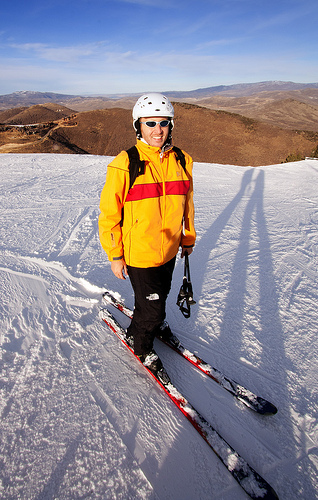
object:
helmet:
[130, 90, 176, 145]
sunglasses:
[146, 118, 171, 128]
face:
[139, 116, 170, 150]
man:
[98, 93, 196, 376]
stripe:
[127, 180, 191, 203]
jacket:
[98, 138, 196, 269]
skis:
[96, 292, 280, 500]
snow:
[0, 152, 316, 499]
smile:
[153, 135, 163, 140]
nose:
[156, 126, 163, 134]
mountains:
[0, 0, 317, 166]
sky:
[0, 0, 318, 102]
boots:
[131, 336, 162, 370]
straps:
[123, 145, 147, 191]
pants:
[127, 256, 175, 354]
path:
[0, 111, 80, 155]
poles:
[177, 251, 197, 318]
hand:
[179, 246, 192, 259]